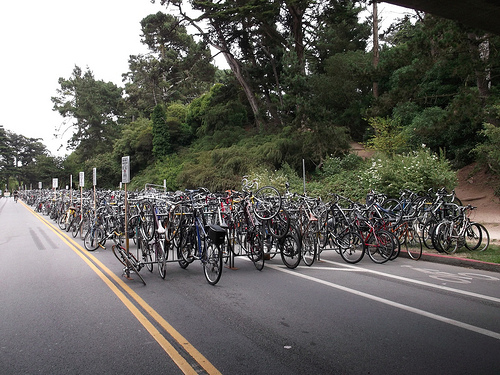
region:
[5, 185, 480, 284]
several bikes parked together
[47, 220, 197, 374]
yellow lines painted on a street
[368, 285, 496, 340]
white lines painted on a street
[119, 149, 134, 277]
a sign at the end of a bike rack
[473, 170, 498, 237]
a dirt trail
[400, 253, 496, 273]
a concrete curb painted red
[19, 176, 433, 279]
many bikes close together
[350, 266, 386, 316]
white lines on road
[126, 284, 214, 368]
yellow lines on road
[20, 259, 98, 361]
road is dark grey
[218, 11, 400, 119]
tall and green trees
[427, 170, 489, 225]
brown ground on hill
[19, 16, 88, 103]
grey and white sky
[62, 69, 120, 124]
green leaves on trees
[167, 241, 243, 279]
black tire on bike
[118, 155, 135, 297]
post next to bikes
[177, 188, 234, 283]
THIS IS A BIKE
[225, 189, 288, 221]
THIS IS A BIKE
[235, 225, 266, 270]
THIS IS A BIKE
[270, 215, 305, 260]
THIS IS A BIKE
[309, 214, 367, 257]
THIS IS A BIKE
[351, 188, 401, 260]
THIS IS A BIKE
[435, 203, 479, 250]
THIS IS A BIKE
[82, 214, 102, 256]
THIS IS A BIKE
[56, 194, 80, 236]
THIS IS A BIKE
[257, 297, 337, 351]
THIS IS A ROAD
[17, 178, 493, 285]
Many bicycles on a road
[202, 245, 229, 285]
Front tire on a bicycle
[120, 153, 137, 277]
A white sign on a pole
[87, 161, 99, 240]
A white sign on a pole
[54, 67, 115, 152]
A green leafy tree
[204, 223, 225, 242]
A storage box on a bicycle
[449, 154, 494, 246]
A dirt path beside a road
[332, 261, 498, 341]
White painted lines on a road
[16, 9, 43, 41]
white clouds in blue sky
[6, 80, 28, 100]
white clouds in blue sky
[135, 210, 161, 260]
bikes parked in slips for race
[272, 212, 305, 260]
bikes parked in slips for race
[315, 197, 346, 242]
bikes parked in slips for race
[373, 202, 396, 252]
bikes parked in slips for race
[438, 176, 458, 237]
bikes parked in slips for race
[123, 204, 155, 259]
bikes parked in slips for race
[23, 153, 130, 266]
row of signs on poles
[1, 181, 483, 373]
parked bicycles on street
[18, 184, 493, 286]
parked bikes on racks